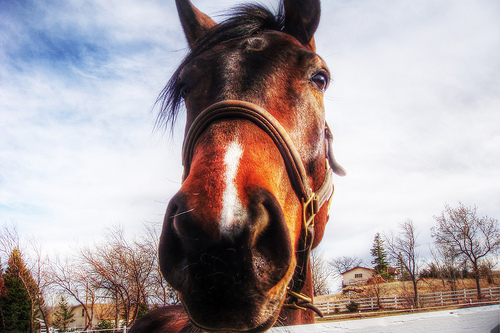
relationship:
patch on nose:
[218, 137, 245, 237] [157, 187, 294, 294]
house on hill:
[343, 232, 444, 318] [0, 275, 499, 328]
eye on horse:
[311, 68, 328, 92] [126, 9, 423, 319]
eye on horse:
[173, 86, 190, 103] [126, 9, 423, 319]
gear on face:
[179, 94, 339, 235] [145, 2, 350, 331]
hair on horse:
[159, 2, 277, 124] [115, 0, 338, 332]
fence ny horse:
[318, 287, 500, 316] [139, 18, 331, 330]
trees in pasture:
[1, 215, 56, 330] [0, 268, 499, 331]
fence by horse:
[318, 289, 498, 316] [158, 2, 332, 331]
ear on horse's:
[168, 1, 215, 40] [98, 0, 355, 332]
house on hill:
[341, 262, 381, 291] [312, 260, 494, 312]